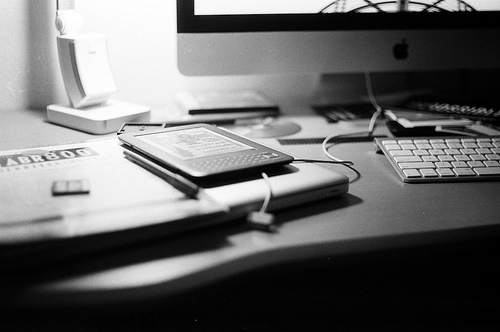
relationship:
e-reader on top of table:
[117, 123, 292, 184] [0, 99, 499, 311]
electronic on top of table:
[374, 128, 498, 186] [0, 99, 499, 311]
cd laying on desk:
[237, 110, 308, 135] [0, 73, 496, 312]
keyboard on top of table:
[371, 136, 499, 185] [0, 99, 499, 311]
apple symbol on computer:
[388, 38, 412, 60] [164, 3, 499, 95]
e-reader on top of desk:
[117, 123, 292, 184] [39, 81, 499, 303]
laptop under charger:
[0, 125, 351, 275] [252, 172, 277, 223]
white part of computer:
[149, 14, 242, 104] [163, 0, 480, 140]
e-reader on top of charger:
[117, 123, 292, 184] [245, 64, 380, 229]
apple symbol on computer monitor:
[390, 38, 410, 59] [174, 3, 499, 73]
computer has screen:
[176, 0, 498, 121] [196, 0, 481, 15]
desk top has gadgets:
[0, 110, 480, 303] [4, 7, 499, 304]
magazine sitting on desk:
[0, 139, 183, 247] [51, 57, 471, 288]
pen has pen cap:
[99, 111, 212, 203] [161, 164, 203, 218]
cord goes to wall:
[260, 104, 383, 214] [0, 0, 494, 117]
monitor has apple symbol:
[187, 13, 475, 121] [388, 38, 412, 60]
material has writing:
[0, 138, 194, 230] [0, 145, 102, 176]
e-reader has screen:
[117, 123, 292, 184] [139, 113, 347, 228]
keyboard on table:
[370, 131, 499, 181] [3, 105, 495, 306]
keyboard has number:
[371, 136, 499, 185] [396, 158, 438, 169]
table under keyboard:
[35, 109, 483, 312] [374, 130, 482, 183]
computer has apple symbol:
[176, 2, 483, 76] [388, 38, 412, 60]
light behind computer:
[139, 23, 171, 74] [171, 0, 498, 187]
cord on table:
[260, 73, 383, 214] [3, 105, 495, 306]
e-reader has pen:
[117, 123, 292, 184] [121, 146, 206, 200]